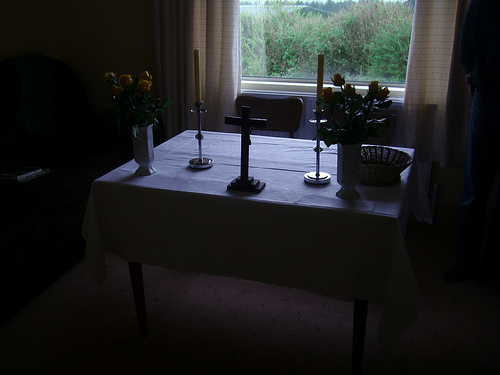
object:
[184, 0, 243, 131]
curtain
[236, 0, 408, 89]
window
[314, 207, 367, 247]
basket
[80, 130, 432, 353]
table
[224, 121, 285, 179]
flowers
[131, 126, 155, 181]
vase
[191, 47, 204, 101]
candle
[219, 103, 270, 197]
crucifix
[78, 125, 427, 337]
table cloth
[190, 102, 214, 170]
candle holder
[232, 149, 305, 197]
chair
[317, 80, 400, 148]
flowers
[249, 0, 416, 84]
trees